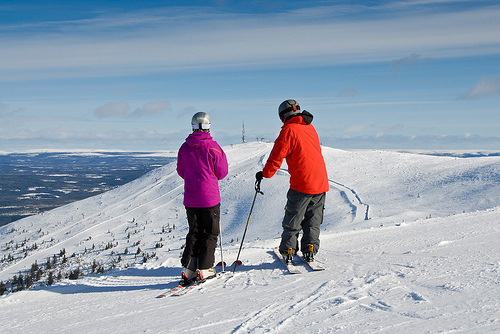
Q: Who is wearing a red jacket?
A: Person on right.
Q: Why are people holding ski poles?
A: To ski.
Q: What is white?
A: Snow.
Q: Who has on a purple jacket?
A: Person on left.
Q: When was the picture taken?
A: Daytime.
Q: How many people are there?
A: Two.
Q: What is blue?
A: Sky.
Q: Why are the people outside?
A: They are skiing.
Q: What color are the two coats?
A: Purple and orange.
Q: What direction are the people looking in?
A: Away from the camera.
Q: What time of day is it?
A: Daytime.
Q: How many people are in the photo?
A: Two.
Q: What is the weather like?
A: Bright and sunny.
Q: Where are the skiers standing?
A: On a snowy mountain.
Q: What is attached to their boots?
A: Skis.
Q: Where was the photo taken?
A: Ski slopes.